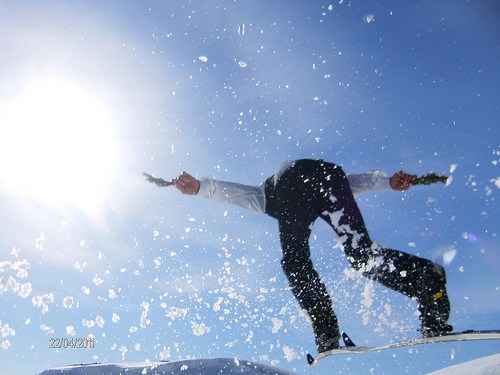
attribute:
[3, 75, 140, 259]
sun — bright, yellow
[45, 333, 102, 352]
date — white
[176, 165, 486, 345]
person — snowboarding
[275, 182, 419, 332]
pants — black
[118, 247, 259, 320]
snow — white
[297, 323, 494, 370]
board — white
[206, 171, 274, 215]
shirt — white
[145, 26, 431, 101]
sky — blue, clear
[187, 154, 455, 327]
man — skiing, white